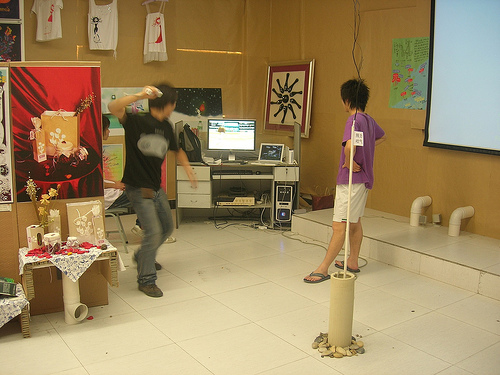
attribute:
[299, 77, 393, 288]
man — standing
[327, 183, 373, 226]
shorts — white, knee length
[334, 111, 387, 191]
shirt — t-shirt, purple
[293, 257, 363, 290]
sandals — flipflops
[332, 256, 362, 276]
sandal — flipflop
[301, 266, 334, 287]
sandal — flipflop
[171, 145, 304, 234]
desk — computer desk, table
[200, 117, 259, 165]
monitor — largish, on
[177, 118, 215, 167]
backpack — black, upright, grey+black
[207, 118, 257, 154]
screen — *not* tv screen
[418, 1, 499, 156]
screen — white, *not* whiteboard, pull-down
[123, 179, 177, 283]
jeans — blue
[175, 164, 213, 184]
drawer — top drawer, open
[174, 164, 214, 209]
drawers — three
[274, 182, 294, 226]
pc — tower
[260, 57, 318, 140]
picture — hanging, maybe painting, probably print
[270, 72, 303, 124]
rays — ten, black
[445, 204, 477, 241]
pipe — plastic, curved, white, cream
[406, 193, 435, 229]
pipe — plastic, curved, white, cream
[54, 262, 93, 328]
base — pipe, plastic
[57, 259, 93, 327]
pipe — plastic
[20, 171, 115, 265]
lively items — tan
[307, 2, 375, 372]
folk art — maybe this [?]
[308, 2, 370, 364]
conceptual art — more likely [if art]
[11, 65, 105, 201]
picture — maybe painting, maybe photograph, maybe poster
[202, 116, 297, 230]
game — electronic game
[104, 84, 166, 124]
arm — lifted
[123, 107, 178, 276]
body — twisted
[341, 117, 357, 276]
pole — white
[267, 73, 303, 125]
swirl — black, circular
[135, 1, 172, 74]
garment — white, shirt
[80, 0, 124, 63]
garment — white, shirt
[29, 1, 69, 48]
garment — white, shirt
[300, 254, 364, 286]
feet — akimbo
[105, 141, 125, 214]
shirt — white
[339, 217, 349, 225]
tag — red+green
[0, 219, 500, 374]
tiles — white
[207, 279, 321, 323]
tile — white, square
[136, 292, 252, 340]
tile — white, square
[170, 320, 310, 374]
tile — white, square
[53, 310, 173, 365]
tile — white, square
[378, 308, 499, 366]
tile — white, square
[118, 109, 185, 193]
shirt — black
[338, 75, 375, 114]
hair — black, spiky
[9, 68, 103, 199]
background — red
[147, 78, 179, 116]
hair — dark brown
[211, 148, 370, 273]
cords — messy, accdnt w8ng 2 happn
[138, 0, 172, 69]
shirt — hanging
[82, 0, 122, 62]
shirt — hanging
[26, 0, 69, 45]
shirt — hanging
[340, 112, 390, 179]
arms — akimbo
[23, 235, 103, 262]
petals — maybe plastic, maybe real, rose red